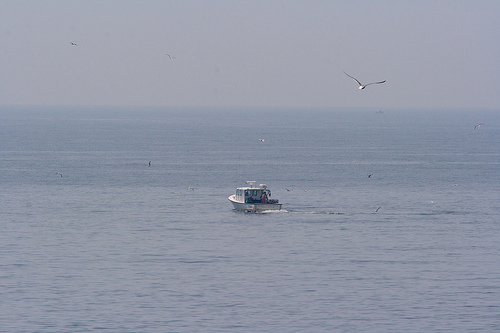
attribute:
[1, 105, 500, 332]
water — blue, pale blue, beautiful, calm, clear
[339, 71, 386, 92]
bird — flying, looking, white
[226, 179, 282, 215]
boat — white, heading out, alone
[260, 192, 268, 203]
people — fishing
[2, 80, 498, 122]
horizon — hazy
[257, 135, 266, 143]
boat — distant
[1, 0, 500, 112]
sky — blue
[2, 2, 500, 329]
weather — perfect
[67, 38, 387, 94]
birds — swarm